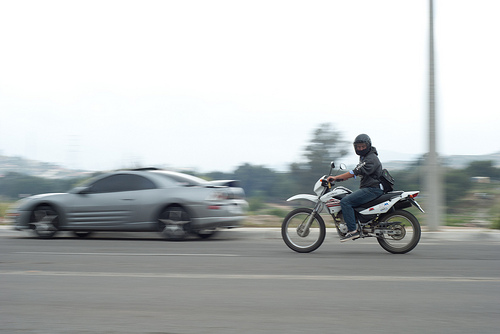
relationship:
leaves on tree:
[250, 169, 272, 183] [233, 149, 292, 201]